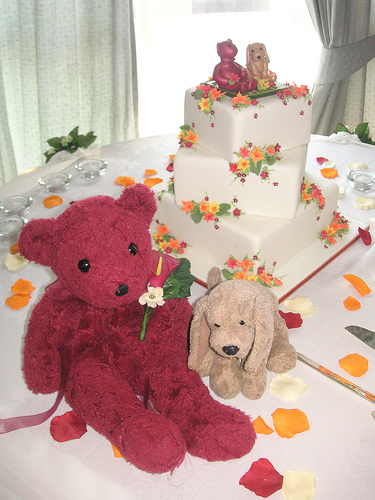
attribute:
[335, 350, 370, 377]
petal — orange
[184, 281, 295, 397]
animal — brown, fuzzy, stuffed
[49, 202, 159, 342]
stuffed animal — bigger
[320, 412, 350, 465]
tablecloth — white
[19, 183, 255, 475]
bear — stuffed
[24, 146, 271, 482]
animal — stuffed, red, fuzzy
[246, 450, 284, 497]
flower — red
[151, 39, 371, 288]
wedding cake — decorated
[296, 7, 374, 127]
curtain — open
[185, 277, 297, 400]
toys — red, brown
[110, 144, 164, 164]
tablecloth — white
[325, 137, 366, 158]
tablecloth — white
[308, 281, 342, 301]
tablecloth — white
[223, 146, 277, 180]
flower — white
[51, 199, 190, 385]
teddy bear — red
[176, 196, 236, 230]
flowers — orange, red, yellow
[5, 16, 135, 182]
curtains — light green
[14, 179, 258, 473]
animal — fuzzy, stuffed, red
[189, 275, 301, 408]
animal — brown, fuzzy, stuffed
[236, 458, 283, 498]
rose petal — red